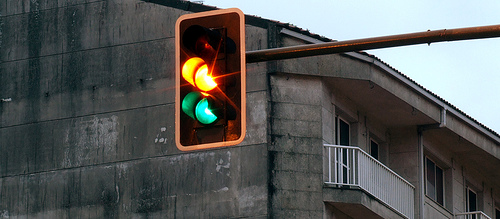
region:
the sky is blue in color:
[433, 45, 495, 87]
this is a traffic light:
[174, 27, 244, 142]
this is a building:
[16, 22, 149, 189]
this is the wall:
[286, 92, 336, 185]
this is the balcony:
[320, 131, 420, 197]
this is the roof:
[389, 62, 426, 79]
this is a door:
[338, 112, 355, 152]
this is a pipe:
[418, 122, 433, 217]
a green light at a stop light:
[176, 90, 225, 130]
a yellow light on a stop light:
[183, 49, 223, 93]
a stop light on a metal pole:
[174, 8, 249, 155]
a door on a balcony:
[332, 114, 352, 184]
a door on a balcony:
[417, 149, 450, 217]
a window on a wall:
[367, 129, 382, 179]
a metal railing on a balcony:
[323, 142, 417, 217]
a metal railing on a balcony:
[453, 209, 498, 217]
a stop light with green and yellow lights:
[166, 10, 251, 156]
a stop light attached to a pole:
[169, 12, 499, 155]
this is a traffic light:
[174, 11, 245, 151]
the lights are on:
[180, 19, 233, 141]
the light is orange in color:
[189, 56, 219, 91]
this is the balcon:
[336, 146, 403, 191]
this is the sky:
[447, 47, 497, 96]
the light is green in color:
[187, 92, 219, 122]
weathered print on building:
[270, 103, 292, 119]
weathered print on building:
[295, 102, 322, 117]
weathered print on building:
[308, 122, 321, 136]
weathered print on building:
[293, 135, 320, 151]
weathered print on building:
[271, 150, 307, 170]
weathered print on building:
[276, 171, 297, 188]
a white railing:
[323, 143, 421, 208]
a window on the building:
[338, 114, 350, 139]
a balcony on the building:
[325, 120, 427, 214]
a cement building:
[11, 6, 261, 214]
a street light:
[167, 13, 499, 146]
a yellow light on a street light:
[190, 58, 221, 86]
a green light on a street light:
[190, 97, 216, 117]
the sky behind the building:
[253, 1, 499, 111]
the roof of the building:
[363, 53, 438, 87]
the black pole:
[253, 19, 499, 72]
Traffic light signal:
[172, 8, 250, 148]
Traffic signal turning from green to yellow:
[168, 10, 248, 146]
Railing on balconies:
[328, 144, 496, 216]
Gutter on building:
[417, 102, 452, 216]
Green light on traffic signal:
[181, 91, 227, 126]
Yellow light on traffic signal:
[181, 54, 219, 89]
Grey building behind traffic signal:
[3, 3, 493, 216]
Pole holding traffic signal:
[249, 23, 498, 62]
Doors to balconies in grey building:
[333, 108, 489, 215]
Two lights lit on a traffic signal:
[178, 16, 250, 150]